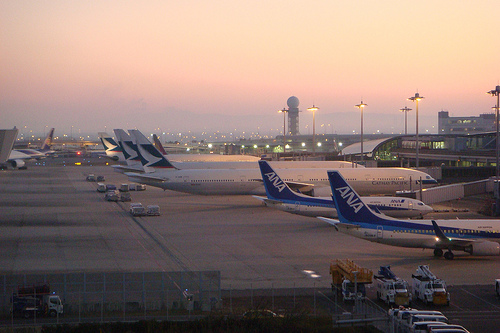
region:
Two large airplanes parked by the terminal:
[110, 128, 436, 211]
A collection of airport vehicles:
[91, 173, 163, 221]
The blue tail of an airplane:
[324, 169, 377, 226]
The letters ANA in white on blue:
[266, 164, 283, 200]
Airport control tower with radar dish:
[281, 92, 307, 142]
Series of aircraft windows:
[391, 224, 433, 238]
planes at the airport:
[87, 125, 484, 268]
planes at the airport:
[92, 110, 433, 276]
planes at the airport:
[94, 120, 479, 232]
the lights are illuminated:
[269, 93, 434, 115]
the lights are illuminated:
[268, 88, 439, 125]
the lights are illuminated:
[254, 80, 446, 130]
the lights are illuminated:
[270, 89, 446, 129]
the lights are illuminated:
[261, 80, 437, 117]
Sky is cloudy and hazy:
[12, 5, 495, 181]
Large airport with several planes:
[5, 4, 498, 330]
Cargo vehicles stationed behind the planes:
[79, 153, 179, 241]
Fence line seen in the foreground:
[9, 254, 499, 324]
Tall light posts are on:
[268, 86, 493, 114]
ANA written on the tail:
[315, 168, 495, 265]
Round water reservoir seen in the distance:
[283, 91, 303, 148]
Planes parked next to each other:
[86, 124, 444, 211]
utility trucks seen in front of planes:
[320, 242, 466, 322]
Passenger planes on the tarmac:
[8, 95, 483, 280]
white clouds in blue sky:
[144, 62, 196, 113]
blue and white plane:
[325, 168, 495, 259]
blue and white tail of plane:
[241, 156, 325, 233]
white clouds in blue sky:
[388, 9, 443, 64]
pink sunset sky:
[0, 0, 498, 133]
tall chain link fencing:
[0, 267, 392, 331]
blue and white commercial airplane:
[315, 168, 499, 263]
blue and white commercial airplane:
[251, 158, 436, 220]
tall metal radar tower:
[284, 92, 301, 136]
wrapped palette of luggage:
[145, 202, 162, 217]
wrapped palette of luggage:
[104, 190, 119, 203]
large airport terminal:
[336, 108, 498, 183]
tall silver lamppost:
[355, 98, 368, 162]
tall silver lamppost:
[308, 101, 320, 158]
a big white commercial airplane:
[112, 125, 452, 217]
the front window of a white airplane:
[413, 164, 438, 184]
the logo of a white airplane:
[370, 176, 407, 189]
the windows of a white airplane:
[288, 169, 330, 191]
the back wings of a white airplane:
[120, 169, 183, 198]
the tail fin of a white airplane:
[125, 127, 176, 180]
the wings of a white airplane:
[426, 225, 476, 257]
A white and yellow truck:
[289, 247, 378, 329]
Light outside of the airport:
[266, 77, 443, 161]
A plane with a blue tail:
[271, 187, 471, 277]